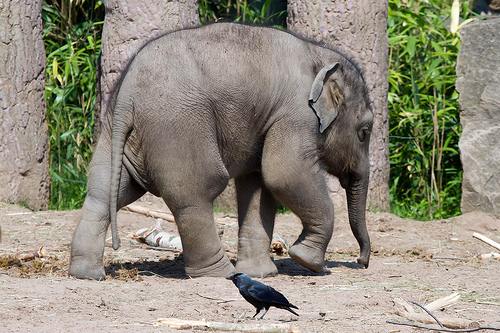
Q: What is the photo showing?
A: It is showing a road.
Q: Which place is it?
A: It is a road.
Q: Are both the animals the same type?
A: No, they are birds and elephants.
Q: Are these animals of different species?
A: Yes, they are birds and elephants.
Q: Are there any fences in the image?
A: No, there are no fences.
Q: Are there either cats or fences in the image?
A: No, there are no fences or cats.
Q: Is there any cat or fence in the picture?
A: No, there are no fences or cats.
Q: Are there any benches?
A: No, there are no benches.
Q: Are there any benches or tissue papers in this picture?
A: No, there are no benches or tissue papers.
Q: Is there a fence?
A: No, there are no fences.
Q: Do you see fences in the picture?
A: No, there are no fences.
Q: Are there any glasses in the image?
A: No, there are no glasses.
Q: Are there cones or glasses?
A: No, there are no glasses or cones.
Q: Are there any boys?
A: No, there are no boys.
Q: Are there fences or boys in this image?
A: No, there are no boys or fences.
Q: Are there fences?
A: No, there are no fences.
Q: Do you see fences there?
A: No, there are no fences.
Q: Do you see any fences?
A: No, there are no fences.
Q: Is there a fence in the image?
A: No, there are no fences.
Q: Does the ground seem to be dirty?
A: Yes, the ground is dirty.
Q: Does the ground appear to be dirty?
A: Yes, the ground is dirty.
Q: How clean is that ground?
A: The ground is dirty.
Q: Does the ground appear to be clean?
A: No, the ground is dirty.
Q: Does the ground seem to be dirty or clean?
A: The ground is dirty.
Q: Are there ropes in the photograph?
A: No, there are no ropes.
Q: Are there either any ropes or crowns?
A: No, there are no ropes or crowns.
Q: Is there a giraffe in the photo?
A: No, there are no giraffes.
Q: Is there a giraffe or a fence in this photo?
A: No, there are no giraffes or fences.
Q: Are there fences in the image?
A: No, there are no fences.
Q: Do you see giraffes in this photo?
A: No, there are no giraffes.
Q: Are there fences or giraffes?
A: No, there are no giraffes or fences.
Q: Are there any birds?
A: Yes, there is a bird.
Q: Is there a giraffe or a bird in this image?
A: Yes, there is a bird.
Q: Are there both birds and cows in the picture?
A: No, there is a bird but no cows.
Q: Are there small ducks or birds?
A: Yes, there is a small bird.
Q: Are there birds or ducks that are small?
A: Yes, the bird is small.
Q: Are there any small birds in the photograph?
A: Yes, there is a small bird.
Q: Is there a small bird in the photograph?
A: Yes, there is a small bird.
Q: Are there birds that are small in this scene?
A: Yes, there is a small bird.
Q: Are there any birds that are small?
A: Yes, there is a bird that is small.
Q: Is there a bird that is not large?
A: Yes, there is a small bird.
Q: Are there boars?
A: No, there are no boars.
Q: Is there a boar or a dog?
A: No, there are no boars or dogs.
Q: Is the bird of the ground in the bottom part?
A: Yes, the bird is in the bottom of the image.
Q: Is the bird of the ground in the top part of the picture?
A: No, the bird is in the bottom of the image.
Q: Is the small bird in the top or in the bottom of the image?
A: The bird is in the bottom of the image.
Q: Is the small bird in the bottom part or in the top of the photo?
A: The bird is in the bottom of the image.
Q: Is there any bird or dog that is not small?
A: No, there is a bird but it is small.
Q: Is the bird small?
A: Yes, the bird is small.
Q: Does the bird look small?
A: Yes, the bird is small.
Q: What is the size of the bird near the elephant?
A: The bird is small.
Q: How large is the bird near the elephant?
A: The bird is small.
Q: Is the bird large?
A: No, the bird is small.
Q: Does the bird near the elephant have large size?
A: No, the bird is small.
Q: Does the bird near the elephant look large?
A: No, the bird is small.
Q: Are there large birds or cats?
A: No, there is a bird but it is small.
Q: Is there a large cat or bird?
A: No, there is a bird but it is small.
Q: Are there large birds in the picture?
A: No, there is a bird but it is small.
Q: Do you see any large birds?
A: No, there is a bird but it is small.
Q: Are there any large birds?
A: No, there is a bird but it is small.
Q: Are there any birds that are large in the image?
A: No, there is a bird but it is small.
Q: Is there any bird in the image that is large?
A: No, there is a bird but it is small.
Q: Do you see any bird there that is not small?
A: No, there is a bird but it is small.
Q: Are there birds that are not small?
A: No, there is a bird but it is small.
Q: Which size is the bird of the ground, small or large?
A: The bird is small.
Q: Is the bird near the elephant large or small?
A: The bird is small.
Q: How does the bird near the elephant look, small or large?
A: The bird is small.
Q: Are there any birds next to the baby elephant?
A: Yes, there is a bird next to the elephant.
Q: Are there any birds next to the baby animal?
A: Yes, there is a bird next to the elephant.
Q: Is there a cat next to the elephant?
A: No, there is a bird next to the elephant.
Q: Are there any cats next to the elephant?
A: No, there is a bird next to the elephant.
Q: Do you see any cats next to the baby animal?
A: No, there is a bird next to the elephant.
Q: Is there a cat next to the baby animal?
A: No, there is a bird next to the elephant.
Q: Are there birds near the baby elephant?
A: Yes, there is a bird near the elephant.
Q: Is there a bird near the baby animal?
A: Yes, there is a bird near the elephant.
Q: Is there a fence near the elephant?
A: No, there is a bird near the elephant.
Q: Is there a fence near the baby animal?
A: No, there is a bird near the elephant.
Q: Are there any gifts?
A: No, there are no gifts.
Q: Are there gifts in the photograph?
A: No, there are no gifts.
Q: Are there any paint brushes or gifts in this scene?
A: No, there are no gifts or paint brushes.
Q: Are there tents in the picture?
A: No, there are no tents.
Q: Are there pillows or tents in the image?
A: No, there are no tents or pillows.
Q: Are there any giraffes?
A: No, there are no giraffes.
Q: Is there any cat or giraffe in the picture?
A: No, there are no giraffes or cats.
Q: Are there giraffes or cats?
A: No, there are no giraffes or cats.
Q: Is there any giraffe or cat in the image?
A: No, there are no giraffes or cats.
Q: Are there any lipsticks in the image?
A: No, there are no lipsticks.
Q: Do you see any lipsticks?
A: No, there are no lipsticks.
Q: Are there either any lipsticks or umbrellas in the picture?
A: No, there are no lipsticks or umbrellas.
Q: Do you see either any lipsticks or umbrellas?
A: No, there are no lipsticks or umbrellas.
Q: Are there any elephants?
A: Yes, there is an elephant.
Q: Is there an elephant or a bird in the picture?
A: Yes, there is an elephant.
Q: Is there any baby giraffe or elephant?
A: Yes, there is a baby elephant.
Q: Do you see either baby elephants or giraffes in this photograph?
A: Yes, there is a baby elephant.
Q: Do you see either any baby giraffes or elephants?
A: Yes, there is a baby elephant.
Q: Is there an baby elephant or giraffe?
A: Yes, there is a baby elephant.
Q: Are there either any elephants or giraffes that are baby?
A: Yes, the elephant is a baby.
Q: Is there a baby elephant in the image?
A: Yes, there is a baby elephant.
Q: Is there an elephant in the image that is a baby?
A: Yes, there is an elephant that is a baby.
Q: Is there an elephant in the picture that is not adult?
A: Yes, there is an baby elephant.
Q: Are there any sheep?
A: No, there are no sheep.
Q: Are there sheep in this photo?
A: No, there are no sheep.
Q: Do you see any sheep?
A: No, there are no sheep.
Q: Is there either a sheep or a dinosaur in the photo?
A: No, there are no sheep or dinosaurs.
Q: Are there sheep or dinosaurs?
A: No, there are no sheep or dinosaurs.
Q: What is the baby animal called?
A: The animal is an elephant.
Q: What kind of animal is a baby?
A: The animal is an elephant.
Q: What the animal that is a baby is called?
A: The animal is an elephant.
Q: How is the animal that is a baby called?
A: The animal is an elephant.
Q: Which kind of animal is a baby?
A: The animal is an elephant.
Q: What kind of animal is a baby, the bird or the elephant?
A: The elephant is a baby.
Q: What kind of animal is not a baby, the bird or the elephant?
A: The bird is not a baby.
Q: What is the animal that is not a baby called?
A: The animal is a bird.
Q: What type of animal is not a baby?
A: The animal is a bird.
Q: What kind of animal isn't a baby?
A: The animal is a bird.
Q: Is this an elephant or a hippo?
A: This is an elephant.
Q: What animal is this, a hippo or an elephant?
A: This is an elephant.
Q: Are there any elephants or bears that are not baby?
A: No, there is an elephant but it is a baby.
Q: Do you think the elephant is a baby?
A: Yes, the elephant is a baby.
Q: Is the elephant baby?
A: Yes, the elephant is a baby.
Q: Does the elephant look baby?
A: Yes, the elephant is a baby.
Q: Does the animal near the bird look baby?
A: Yes, the elephant is a baby.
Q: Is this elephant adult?
A: No, the elephant is a baby.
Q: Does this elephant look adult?
A: No, the elephant is a baby.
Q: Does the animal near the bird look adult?
A: No, the elephant is a baby.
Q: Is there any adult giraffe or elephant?
A: No, there is an elephant but it is a baby.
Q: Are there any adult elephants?
A: No, there is an elephant but it is a baby.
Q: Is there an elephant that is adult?
A: No, there is an elephant but it is a baby.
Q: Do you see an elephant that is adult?
A: No, there is an elephant but it is a baby.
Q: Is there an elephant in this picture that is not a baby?
A: No, there is an elephant but it is a baby.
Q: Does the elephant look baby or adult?
A: The elephant is a baby.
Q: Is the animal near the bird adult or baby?
A: The elephant is a baby.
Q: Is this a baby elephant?
A: Yes, this is a baby elephant.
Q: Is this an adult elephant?
A: No, this is a baby elephant.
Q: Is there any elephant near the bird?
A: Yes, there is an elephant near the bird.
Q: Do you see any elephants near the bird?
A: Yes, there is an elephant near the bird.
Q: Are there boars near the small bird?
A: No, there is an elephant near the bird.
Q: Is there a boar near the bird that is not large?
A: No, there is an elephant near the bird.